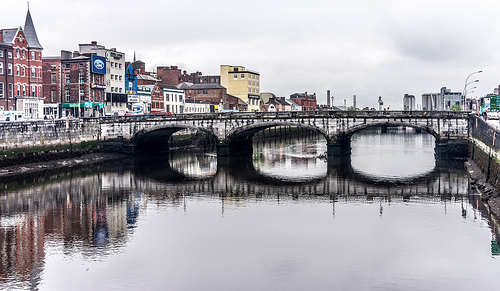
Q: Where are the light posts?
A: In the distance on the right.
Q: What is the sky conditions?
A: Cloudy.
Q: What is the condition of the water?
A: Very calm.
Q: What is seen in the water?
A: The reflection of the bridge.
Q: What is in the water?
A: Bridge.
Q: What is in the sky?
A: Clouds.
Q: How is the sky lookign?
A: Clear.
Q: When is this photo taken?
A: Daytime.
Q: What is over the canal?
A: A bridge.